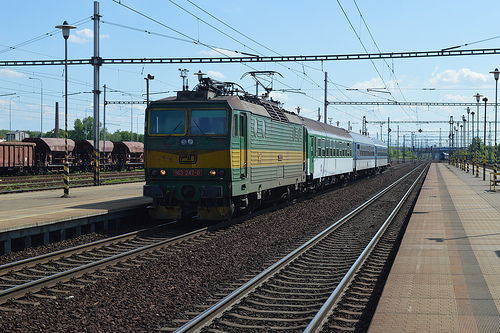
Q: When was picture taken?
A: During daylight.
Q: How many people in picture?
A: None.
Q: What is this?
A: A train.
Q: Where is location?
A: In a train yard.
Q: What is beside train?
A: A walkway.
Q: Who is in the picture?
A: No one.